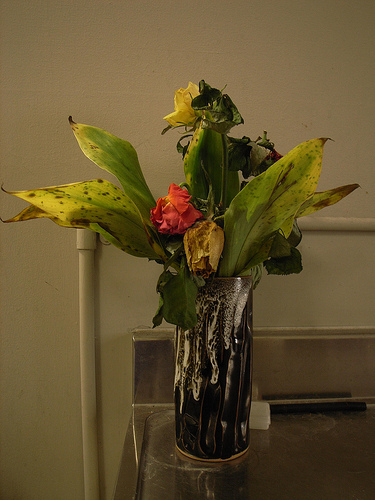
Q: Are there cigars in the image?
A: No, there are no cigars.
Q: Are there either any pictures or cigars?
A: No, there are no cigars or pictures.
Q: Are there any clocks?
A: No, there are no clocks.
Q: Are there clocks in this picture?
A: No, there are no clocks.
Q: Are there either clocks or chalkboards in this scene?
A: No, there are no clocks or chalkboards.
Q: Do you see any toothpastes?
A: No, there are no toothpastes.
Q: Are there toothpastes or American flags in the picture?
A: No, there are no toothpastes or American flags.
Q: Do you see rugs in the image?
A: No, there are no rugs.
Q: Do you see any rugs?
A: No, there are no rugs.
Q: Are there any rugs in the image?
A: No, there are no rugs.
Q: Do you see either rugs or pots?
A: No, there are no rugs or pots.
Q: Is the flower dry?
A: Yes, the flower is dry.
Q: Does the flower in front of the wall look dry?
A: Yes, the flower is dry.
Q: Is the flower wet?
A: No, the flower is dry.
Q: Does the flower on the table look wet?
A: No, the flower is dry.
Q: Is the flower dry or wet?
A: The flower is dry.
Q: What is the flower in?
A: The flower is in the vase.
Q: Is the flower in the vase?
A: Yes, the flower is in the vase.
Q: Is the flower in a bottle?
A: No, the flower is in the vase.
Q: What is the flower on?
A: The flower is on the table.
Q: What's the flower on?
A: The flower is on the table.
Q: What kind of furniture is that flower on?
A: The flower is on the table.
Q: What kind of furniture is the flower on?
A: The flower is on the table.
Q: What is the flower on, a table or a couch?
A: The flower is on a table.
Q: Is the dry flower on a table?
A: Yes, the flower is on a table.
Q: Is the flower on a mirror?
A: No, the flower is on a table.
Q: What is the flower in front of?
A: The flower is in front of the wall.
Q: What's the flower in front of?
A: The flower is in front of the wall.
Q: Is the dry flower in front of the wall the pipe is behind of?
A: Yes, the flower is in front of the wall.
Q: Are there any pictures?
A: No, there are no pictures.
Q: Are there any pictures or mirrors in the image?
A: No, there are no pictures or mirrors.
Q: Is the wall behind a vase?
A: Yes, the wall is behind a vase.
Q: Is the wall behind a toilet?
A: No, the wall is behind a vase.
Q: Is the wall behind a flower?
A: Yes, the wall is behind a flower.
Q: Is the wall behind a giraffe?
A: No, the wall is behind a flower.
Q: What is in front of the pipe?
A: The wall is in front of the pipe.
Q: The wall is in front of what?
A: The wall is in front of the pipe.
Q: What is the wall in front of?
A: The wall is in front of the pipe.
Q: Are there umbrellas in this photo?
A: No, there are no umbrellas.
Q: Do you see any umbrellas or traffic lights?
A: No, there are no umbrellas or traffic lights.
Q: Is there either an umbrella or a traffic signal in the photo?
A: No, there are no umbrellas or traffic lights.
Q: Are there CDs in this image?
A: No, there are no cds.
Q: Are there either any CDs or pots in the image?
A: No, there are no CDs or pots.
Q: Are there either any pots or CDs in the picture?
A: No, there are no CDs or pots.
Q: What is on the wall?
A: The pipe is on the wall.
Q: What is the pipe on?
A: The pipe is on the wall.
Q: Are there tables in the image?
A: Yes, there is a table.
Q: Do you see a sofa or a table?
A: Yes, there is a table.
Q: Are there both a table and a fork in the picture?
A: No, there is a table but no forks.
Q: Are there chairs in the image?
A: No, there are no chairs.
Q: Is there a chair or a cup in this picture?
A: No, there are no chairs or cups.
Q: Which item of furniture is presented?
A: The piece of furniture is a table.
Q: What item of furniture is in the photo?
A: The piece of furniture is a table.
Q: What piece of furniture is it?
A: The piece of furniture is a table.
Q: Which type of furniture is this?
A: This is a table.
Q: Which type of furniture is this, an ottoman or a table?
A: This is a table.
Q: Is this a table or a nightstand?
A: This is a table.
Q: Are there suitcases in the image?
A: No, there are no suitcases.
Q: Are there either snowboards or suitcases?
A: No, there are no suitcases or snowboards.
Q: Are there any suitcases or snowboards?
A: No, there are no suitcases or snowboards.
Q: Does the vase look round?
A: Yes, the vase is round.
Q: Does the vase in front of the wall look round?
A: Yes, the vase is round.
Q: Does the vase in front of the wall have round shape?
A: Yes, the vase is round.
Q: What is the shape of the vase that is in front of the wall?
A: The vase is round.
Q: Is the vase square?
A: No, the vase is round.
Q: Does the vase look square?
A: No, the vase is round.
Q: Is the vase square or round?
A: The vase is round.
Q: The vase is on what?
A: The vase is on the table.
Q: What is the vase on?
A: The vase is on the table.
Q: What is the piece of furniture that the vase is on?
A: The piece of furniture is a table.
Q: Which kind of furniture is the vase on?
A: The vase is on the table.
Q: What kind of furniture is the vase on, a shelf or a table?
A: The vase is on a table.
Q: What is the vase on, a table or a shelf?
A: The vase is on a table.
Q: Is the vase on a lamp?
A: No, the vase is on the table.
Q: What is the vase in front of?
A: The vase is in front of the wall.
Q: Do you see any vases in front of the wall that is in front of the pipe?
A: Yes, there is a vase in front of the wall.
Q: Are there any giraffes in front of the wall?
A: No, there is a vase in front of the wall.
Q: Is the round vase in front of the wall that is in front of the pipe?
A: Yes, the vase is in front of the wall.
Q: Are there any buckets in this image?
A: No, there are no buckets.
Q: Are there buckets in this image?
A: No, there are no buckets.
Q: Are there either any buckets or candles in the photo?
A: No, there are no buckets or candles.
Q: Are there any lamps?
A: No, there are no lamps.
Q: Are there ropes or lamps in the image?
A: No, there are no lamps or ropes.